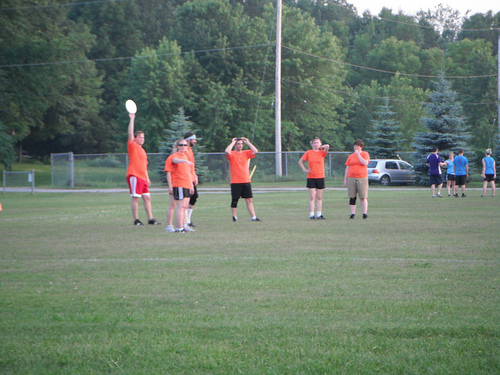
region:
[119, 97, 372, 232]
seven frisbee players on the same team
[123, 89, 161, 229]
man is holding up a yellow frisbee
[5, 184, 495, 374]
large green field for playing frisbee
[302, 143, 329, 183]
bright orange shirt on the woman frisbee player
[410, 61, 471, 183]
a blue-green pine tree next to the parking lot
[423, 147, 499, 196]
four frisbee players in the background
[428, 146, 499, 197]
four frisbee players wearing blue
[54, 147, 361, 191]
a chain link fence behind the field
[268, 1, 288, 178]
a white pole holding wires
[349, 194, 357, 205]
this woman has a black knee brace on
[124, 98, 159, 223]
A man stretching on a field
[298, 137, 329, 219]
A girl playing sports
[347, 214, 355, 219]
A black shoe worn on a foot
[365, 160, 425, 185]
A silver car parked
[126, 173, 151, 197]
Red shorts worn by a man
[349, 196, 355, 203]
A black knee brace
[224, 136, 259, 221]
A man playing sports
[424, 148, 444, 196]
A mean wearing a purple shirt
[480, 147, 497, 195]
A girl wearing a light bue shirt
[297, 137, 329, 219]
A woman wearing an orange shirt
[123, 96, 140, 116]
Frisbee in the hand.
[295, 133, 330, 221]
Black shorts on the girl.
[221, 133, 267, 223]
Black knee brace on the man.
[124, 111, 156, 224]
Red shorts on the person.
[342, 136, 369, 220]
Brown shorts on the person.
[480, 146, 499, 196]
Blue shirt on the woman.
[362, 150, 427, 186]
Silver color car in the background.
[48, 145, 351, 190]
chain link fence in the background.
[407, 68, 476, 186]
Pine tree in the background.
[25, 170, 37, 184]
White sign on the fence.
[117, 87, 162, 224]
a boy holding a frisbee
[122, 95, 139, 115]
the frisbee is yellow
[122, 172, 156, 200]
his shorts are red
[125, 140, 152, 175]
his shirt is orange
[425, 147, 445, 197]
this person has a dark blue shirt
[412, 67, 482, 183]
a blue spruce behind the people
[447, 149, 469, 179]
a boy in a blue shirt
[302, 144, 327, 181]
a girl in an orange shirt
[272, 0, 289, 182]
a telephone pole behind the fence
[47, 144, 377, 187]
this fence is metal